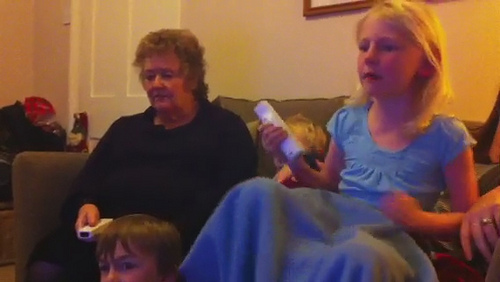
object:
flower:
[26, 94, 57, 123]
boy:
[96, 214, 179, 281]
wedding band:
[482, 219, 492, 226]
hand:
[461, 186, 500, 261]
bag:
[36, 120, 65, 138]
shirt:
[24, 100, 257, 282]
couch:
[12, 95, 498, 281]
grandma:
[24, 29, 258, 282]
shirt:
[177, 100, 477, 281]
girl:
[177, 0, 478, 282]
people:
[24, 0, 500, 280]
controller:
[253, 100, 304, 160]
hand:
[257, 123, 287, 153]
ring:
[479, 210, 492, 228]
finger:
[481, 210, 498, 253]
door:
[65, 0, 181, 153]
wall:
[0, 0, 499, 154]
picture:
[302, 0, 372, 15]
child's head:
[96, 214, 179, 282]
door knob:
[70, 111, 88, 135]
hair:
[345, 4, 454, 135]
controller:
[76, 218, 113, 239]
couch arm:
[12, 151, 91, 269]